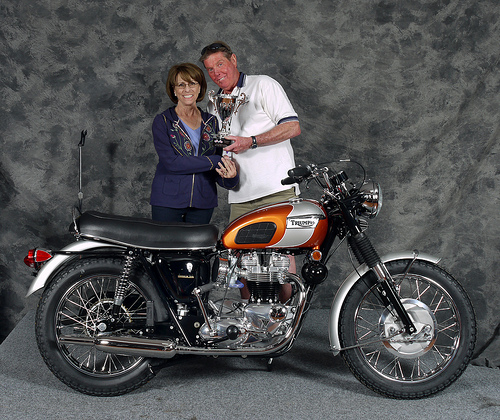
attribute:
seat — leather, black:
[68, 209, 221, 256]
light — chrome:
[355, 177, 392, 218]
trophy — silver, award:
[207, 87, 249, 151]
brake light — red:
[22, 249, 33, 267]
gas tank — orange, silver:
[223, 200, 332, 253]